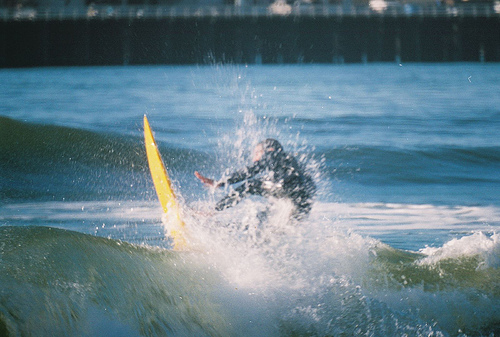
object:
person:
[191, 134, 320, 251]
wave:
[0, 225, 500, 336]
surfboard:
[143, 112, 204, 253]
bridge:
[0, 0, 500, 64]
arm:
[221, 154, 270, 189]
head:
[253, 136, 279, 158]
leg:
[213, 180, 278, 212]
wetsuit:
[212, 148, 319, 227]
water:
[0, 60, 500, 335]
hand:
[190, 170, 218, 189]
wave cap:
[416, 230, 500, 274]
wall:
[0, 12, 500, 67]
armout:
[188, 134, 319, 223]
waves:
[0, 115, 203, 171]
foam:
[198, 200, 324, 290]